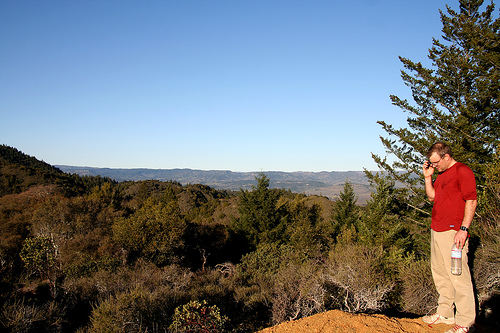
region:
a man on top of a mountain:
[421, 141, 477, 326]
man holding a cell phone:
[421, 159, 435, 176]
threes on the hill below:
[1, 143, 499, 331]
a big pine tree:
[366, 3, 497, 243]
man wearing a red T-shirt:
[428, 163, 475, 238]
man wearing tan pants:
[431, 229, 478, 321]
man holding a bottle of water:
[450, 240, 465, 275]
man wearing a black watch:
[458, 223, 470, 234]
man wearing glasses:
[426, 156, 447, 166]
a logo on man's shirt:
[448, 222, 457, 230]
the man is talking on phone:
[386, 125, 484, 331]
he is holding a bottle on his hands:
[394, 119, 495, 331]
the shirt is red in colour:
[425, 169, 480, 236]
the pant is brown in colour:
[425, 239, 470, 313]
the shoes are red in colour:
[427, 308, 472, 332]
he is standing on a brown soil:
[300, 143, 496, 331]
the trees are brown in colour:
[8, 163, 312, 282]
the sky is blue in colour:
[139, 58, 348, 124]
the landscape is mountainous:
[135, 139, 432, 233]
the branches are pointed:
[370, 36, 492, 142]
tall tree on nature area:
[362, 0, 498, 275]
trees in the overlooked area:
[4, 199, 305, 261]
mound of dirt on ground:
[266, 309, 426, 331]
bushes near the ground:
[273, 249, 429, 311]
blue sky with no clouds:
[16, 20, 356, 125]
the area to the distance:
[142, 163, 321, 181]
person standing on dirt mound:
[413, 135, 488, 332]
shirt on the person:
[416, 168, 482, 225]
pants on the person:
[423, 225, 472, 319]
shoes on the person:
[424, 310, 474, 332]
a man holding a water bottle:
[449, 239, 466, 282]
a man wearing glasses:
[428, 144, 448, 169]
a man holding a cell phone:
[413, 144, 443, 184]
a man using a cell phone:
[416, 147, 456, 181]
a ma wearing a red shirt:
[426, 155, 470, 241]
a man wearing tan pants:
[418, 225, 478, 315]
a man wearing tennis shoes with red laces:
[412, 314, 469, 331]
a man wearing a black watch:
[459, 223, 475, 238]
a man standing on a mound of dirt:
[351, 316, 479, 332]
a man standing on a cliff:
[96, 133, 457, 300]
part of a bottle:
[451, 265, 462, 277]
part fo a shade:
[213, 215, 249, 270]